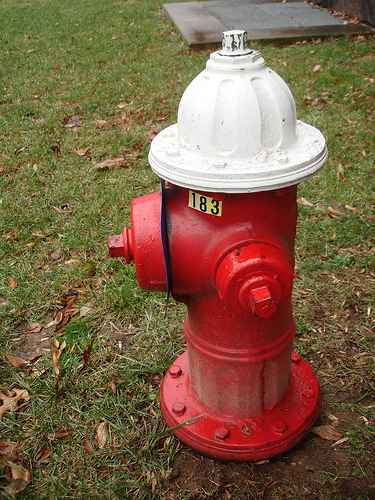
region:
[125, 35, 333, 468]
red and white hydrant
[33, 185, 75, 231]
short green and brown grass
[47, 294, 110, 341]
short green and brown grass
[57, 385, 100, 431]
short green and brown grass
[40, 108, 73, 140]
short green and brown grass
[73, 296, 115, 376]
short green and brown grass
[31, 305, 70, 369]
short green and brown grass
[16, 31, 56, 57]
short green and brown grass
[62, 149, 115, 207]
short green and brown grass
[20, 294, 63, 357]
short green and brown grass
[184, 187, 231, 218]
black text on side of fire hydrant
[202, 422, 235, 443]
red bolt on base of fire hydrant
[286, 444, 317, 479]
brown dirt on ground around hydrant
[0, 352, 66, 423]
brown leaves laying in grass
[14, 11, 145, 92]
green grass growing on ground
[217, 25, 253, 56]
large white bolt on top of hydrant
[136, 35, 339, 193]
white top of fire hydrant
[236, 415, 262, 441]
chip in red paint on fire hydrant base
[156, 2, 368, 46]
concrete slab behind fire hydrant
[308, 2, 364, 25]
leaves laying on concrete slab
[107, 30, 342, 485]
a fire hydrant in the area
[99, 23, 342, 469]
the fire hydrant is red in color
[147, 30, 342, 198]
the top part is white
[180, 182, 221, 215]
numbers are on the fire hydrant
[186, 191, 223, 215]
the numbers are black in color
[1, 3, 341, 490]
the grass in the area is short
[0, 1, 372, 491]
the grass is green and brown in color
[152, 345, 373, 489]
dirt is around the fire hydrant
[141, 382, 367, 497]
the dirt is a dark brown color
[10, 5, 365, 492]
leaves are in the grass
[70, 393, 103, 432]
short brown and green grass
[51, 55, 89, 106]
short brown and green grass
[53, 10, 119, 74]
short brown and green grass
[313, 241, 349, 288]
short brown and green grass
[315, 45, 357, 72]
short brown and green grass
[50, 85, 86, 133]
short brown and green grass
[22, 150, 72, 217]
short brown and green grass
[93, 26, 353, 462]
Red fire hydrant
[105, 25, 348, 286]
Red fire hydrant with white top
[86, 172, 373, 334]
Red fire hydrant with yellow sticker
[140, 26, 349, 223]
white fire hydrant cap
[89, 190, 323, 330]
Red fire hydrant caps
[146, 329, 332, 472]
base of red fire hydrant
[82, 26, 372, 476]
red and white fire hydrant in grass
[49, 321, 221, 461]
Grass at base of fire hydrant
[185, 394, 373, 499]
mud and leaves next to fire hydrant